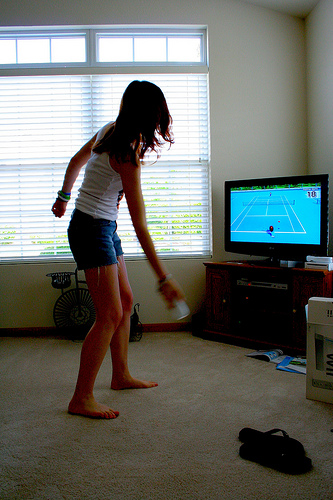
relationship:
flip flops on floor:
[233, 419, 314, 480] [1, 324, 331, 500]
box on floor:
[299, 290, 332, 407] [1, 324, 331, 500]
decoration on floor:
[43, 265, 106, 348] [1, 324, 331, 500]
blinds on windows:
[2, 73, 219, 265] [1, 24, 220, 270]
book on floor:
[246, 342, 286, 372] [1, 324, 331, 500]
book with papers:
[246, 342, 286, 372] [272, 348, 309, 380]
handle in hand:
[159, 282, 195, 322] [154, 275, 186, 311]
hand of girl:
[154, 275, 186, 311] [43, 71, 192, 426]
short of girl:
[62, 210, 130, 274] [43, 71, 192, 426]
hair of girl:
[90, 80, 178, 171] [43, 71, 192, 426]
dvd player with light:
[233, 271, 286, 292] [245, 280, 252, 288]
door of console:
[285, 275, 322, 356] [189, 253, 332, 368]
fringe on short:
[94, 265, 102, 284] [62, 210, 130, 274]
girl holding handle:
[43, 71, 192, 426] [159, 282, 195, 322]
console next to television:
[203, 266, 332, 339] [220, 170, 332, 264]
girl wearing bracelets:
[43, 71, 192, 426] [57, 187, 71, 201]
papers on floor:
[272, 348, 309, 380] [1, 324, 331, 500]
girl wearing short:
[43, 71, 192, 426] [62, 210, 130, 274]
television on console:
[220, 170, 332, 264] [189, 253, 332, 368]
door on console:
[285, 275, 322, 356] [189, 253, 332, 368]